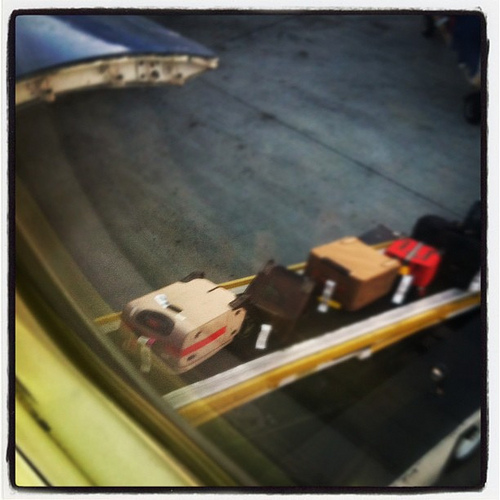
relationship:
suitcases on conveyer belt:
[135, 209, 484, 358] [94, 219, 468, 407]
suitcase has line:
[119, 269, 243, 375] [167, 321, 228, 371]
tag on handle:
[131, 334, 164, 379] [124, 339, 176, 364]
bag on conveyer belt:
[224, 258, 316, 363] [94, 233, 483, 426]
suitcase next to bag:
[119, 269, 243, 375] [224, 258, 316, 363]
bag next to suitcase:
[384, 237, 447, 287] [318, 239, 414, 341]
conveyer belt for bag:
[94, 233, 483, 426] [224, 258, 316, 363]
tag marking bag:
[131, 334, 164, 379] [224, 258, 316, 363]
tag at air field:
[131, 334, 164, 379] [9, 11, 484, 488]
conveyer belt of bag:
[94, 219, 468, 407] [224, 258, 316, 363]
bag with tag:
[224, 258, 316, 363] [131, 334, 164, 379]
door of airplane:
[1, 22, 233, 107] [21, 28, 260, 478]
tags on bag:
[133, 296, 453, 365] [224, 258, 316, 363]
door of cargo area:
[1, 22, 233, 107] [28, 123, 496, 496]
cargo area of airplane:
[28, 123, 496, 496] [21, 28, 260, 478]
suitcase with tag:
[119, 269, 243, 375] [131, 334, 164, 379]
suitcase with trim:
[119, 269, 243, 375] [181, 332, 229, 355]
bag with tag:
[224, 258, 316, 363] [254, 324, 268, 350]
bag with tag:
[384, 237, 447, 287] [401, 272, 423, 300]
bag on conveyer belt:
[224, 258, 316, 363] [94, 219, 468, 407]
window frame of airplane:
[25, 277, 214, 497] [21, 28, 260, 478]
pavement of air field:
[86, 37, 495, 235] [9, 11, 484, 488]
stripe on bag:
[178, 314, 228, 346] [224, 258, 316, 363]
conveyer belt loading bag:
[94, 219, 468, 407] [224, 258, 316, 363]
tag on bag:
[131, 334, 164, 379] [224, 258, 316, 363]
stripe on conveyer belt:
[169, 299, 474, 418] [94, 219, 468, 407]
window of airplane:
[25, 19, 470, 412] [21, 28, 260, 478]